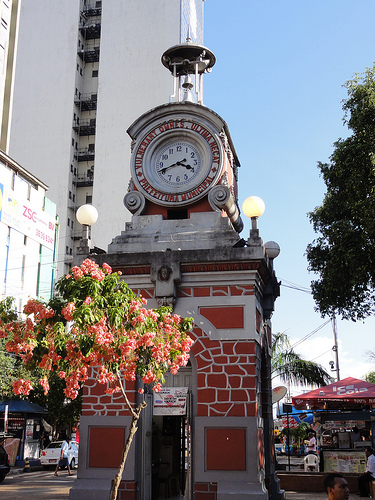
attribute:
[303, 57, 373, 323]
tree — green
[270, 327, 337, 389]
tree — palm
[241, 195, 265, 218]
light — on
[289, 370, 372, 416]
tent — vendors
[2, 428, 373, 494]
street — busy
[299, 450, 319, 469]
chair — plastic, white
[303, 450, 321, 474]
chair — white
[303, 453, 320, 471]
chair — plastic, white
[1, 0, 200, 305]
building — tall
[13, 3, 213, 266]
building — tall, white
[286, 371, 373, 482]
tent — red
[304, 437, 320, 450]
shirt — pink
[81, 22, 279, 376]
monument — red, white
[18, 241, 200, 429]
branch — thin, brown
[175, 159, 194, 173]
hand — hour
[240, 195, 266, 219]
light globe —  light  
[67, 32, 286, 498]
brick tower — brick  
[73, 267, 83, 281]
flowers — pink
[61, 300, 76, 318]
flowers — pink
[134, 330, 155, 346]
flowers — pink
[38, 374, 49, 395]
flowers — pink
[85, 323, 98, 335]
flowers — pink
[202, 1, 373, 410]
sky — blue, clear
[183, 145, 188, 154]
number — black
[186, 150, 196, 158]
number — black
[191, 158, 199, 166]
number — black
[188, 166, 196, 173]
number — black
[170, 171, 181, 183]
number — black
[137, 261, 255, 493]
building — red, white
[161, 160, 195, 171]
hands — black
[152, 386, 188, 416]
poster — white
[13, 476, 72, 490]
lines — traffic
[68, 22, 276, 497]
tower — clock